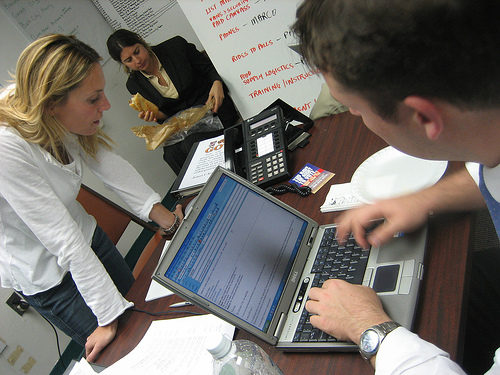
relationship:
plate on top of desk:
[348, 141, 450, 205] [231, 72, 496, 250]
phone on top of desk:
[212, 94, 317, 209] [74, 105, 481, 372]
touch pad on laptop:
[372, 264, 399, 292] [172, 165, 419, 373]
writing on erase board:
[241, 62, 303, 87] [178, 0, 326, 122]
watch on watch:
[336, 299, 410, 371] [359, 321, 402, 367]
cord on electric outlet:
[29, 307, 63, 371] [6, 291, 30, 317]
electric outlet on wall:
[6, 291, 30, 317] [2, 4, 178, 370]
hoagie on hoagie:
[120, 91, 160, 121] [128, 93, 158, 118]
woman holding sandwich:
[0, 29, 226, 362] [124, 91, 161, 119]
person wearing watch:
[305, 4, 496, 372] [337, 328, 417, 340]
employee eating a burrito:
[97, 22, 249, 175] [121, 87, 163, 132]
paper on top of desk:
[109, 307, 241, 373] [83, 110, 477, 375]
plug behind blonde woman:
[17, 300, 30, 312] [0, 33, 183, 362]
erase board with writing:
[181, 6, 326, 121] [201, 85, 274, 99]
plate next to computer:
[348, 141, 450, 205] [151, 165, 429, 353]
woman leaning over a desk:
[0, 29, 226, 362] [74, 105, 481, 372]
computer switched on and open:
[151, 165, 429, 353] [217, 255, 248, 356]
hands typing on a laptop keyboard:
[305, 278, 392, 341] [290, 225, 371, 340]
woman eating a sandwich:
[0, 29, 226, 362] [133, 84, 145, 171]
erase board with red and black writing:
[178, 0, 326, 122] [221, 8, 353, 133]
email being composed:
[171, 194, 267, 351] [290, 278, 340, 375]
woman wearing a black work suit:
[0, 29, 226, 362] [122, 40, 217, 162]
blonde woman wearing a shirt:
[0, 25, 194, 360] [1, 83, 163, 327]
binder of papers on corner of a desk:
[178, 134, 225, 189] [320, 138, 358, 161]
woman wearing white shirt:
[0, 29, 226, 362] [1, 122, 168, 324]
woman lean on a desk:
[0, 29, 226, 362] [74, 105, 481, 372]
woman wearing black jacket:
[113, 23, 235, 178] [124, 39, 234, 141]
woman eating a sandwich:
[0, 29, 226, 362] [125, 78, 157, 118]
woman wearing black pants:
[0, 29, 226, 362] [170, 125, 241, 162]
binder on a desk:
[187, 124, 246, 191] [279, 162, 314, 202]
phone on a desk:
[223, 106, 293, 189] [144, 160, 462, 374]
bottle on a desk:
[204, 332, 284, 374] [74, 105, 481, 372]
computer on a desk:
[151, 165, 429, 353] [74, 105, 481, 372]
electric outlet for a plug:
[2, 288, 31, 317] [15, 299, 32, 311]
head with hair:
[108, 36, 151, 70] [103, 25, 146, 58]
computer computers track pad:
[151, 165, 429, 353] [372, 259, 402, 300]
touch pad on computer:
[370, 263, 401, 295] [151, 164, 431, 350]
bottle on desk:
[198, 329, 284, 374] [74, 105, 481, 372]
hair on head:
[1, 30, 104, 163] [3, 20, 102, 141]